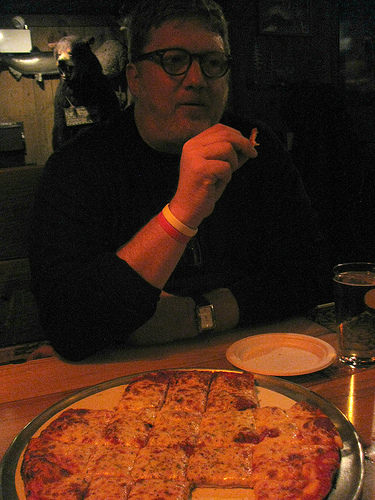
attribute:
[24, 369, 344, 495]
pizza — sliced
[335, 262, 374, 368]
glass — full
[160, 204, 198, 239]
wrist band — pair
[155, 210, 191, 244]
wrist band — pair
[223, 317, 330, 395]
tray — silver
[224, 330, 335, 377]
plate — empty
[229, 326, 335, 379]
plate — paper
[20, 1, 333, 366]
man — sitting down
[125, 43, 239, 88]
glasses — black, rimmed, colorless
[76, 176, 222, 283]
arm — man's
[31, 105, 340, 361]
shirt — black, long sleeved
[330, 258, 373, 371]
glass — tall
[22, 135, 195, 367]
arm — man's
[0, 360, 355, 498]
tray — silver